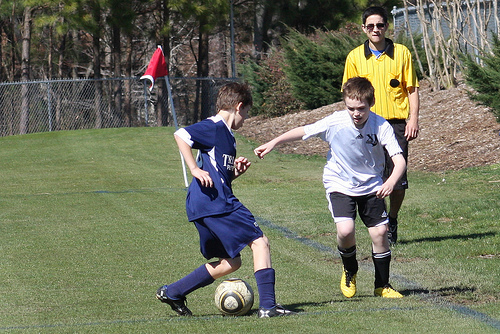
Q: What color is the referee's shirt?
A: Yellow and black.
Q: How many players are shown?
A: Two.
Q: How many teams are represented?
A: Two.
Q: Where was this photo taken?
A: At a soccer field.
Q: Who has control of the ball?
A: The blue player.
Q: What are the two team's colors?
A: Blue and White and White and Black.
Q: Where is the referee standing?
A: Behind the players.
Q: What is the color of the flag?
A: Red.